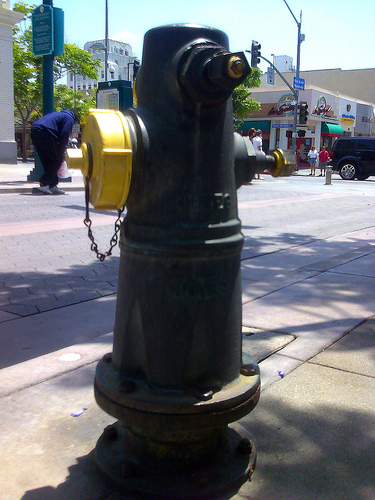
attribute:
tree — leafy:
[57, 49, 96, 111]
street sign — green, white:
[29, 2, 53, 57]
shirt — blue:
[30, 110, 75, 141]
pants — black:
[31, 125, 64, 186]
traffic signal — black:
[296, 98, 309, 126]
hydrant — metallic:
[62, 22, 297, 498]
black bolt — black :
[194, 386, 214, 399]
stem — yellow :
[63, 102, 134, 214]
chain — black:
[77, 168, 122, 256]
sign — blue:
[32, 4, 54, 57]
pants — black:
[23, 101, 82, 201]